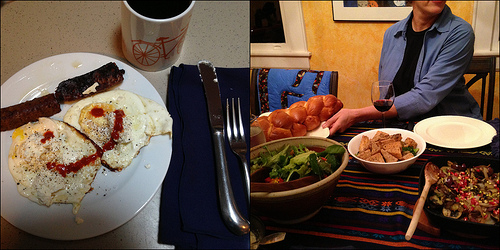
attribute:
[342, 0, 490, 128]
woman — serving, close, white, sitting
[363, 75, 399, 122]
cup — clear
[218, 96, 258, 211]
fork — silver, grey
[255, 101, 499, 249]
table — cloth, white, porcelain, red, brown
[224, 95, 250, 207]
fork — silver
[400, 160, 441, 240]
utensil — wood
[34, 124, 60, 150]
eye — one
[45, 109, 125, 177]
smile — one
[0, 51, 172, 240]
white plate — round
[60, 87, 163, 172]
egg — fried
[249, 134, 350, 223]
bowl — brown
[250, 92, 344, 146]
bread loaf — braided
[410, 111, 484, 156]
dinner plate — empty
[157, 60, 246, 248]
napkin — blue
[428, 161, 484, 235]
dinner entree — vegetable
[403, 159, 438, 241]
spoon — wooden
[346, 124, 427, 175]
bowl — white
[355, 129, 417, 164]
bread — brown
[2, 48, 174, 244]
plate — white, round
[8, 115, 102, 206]
egg — one, fried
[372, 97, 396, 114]
wine — red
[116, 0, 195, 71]
cup — paper